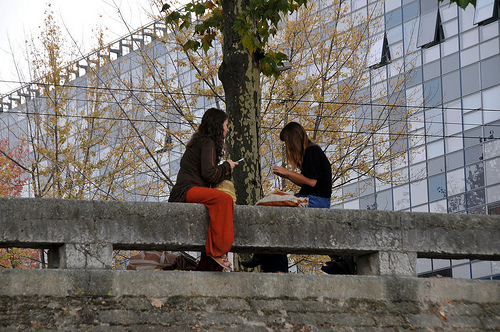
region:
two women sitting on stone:
[166, 105, 333, 270]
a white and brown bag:
[256, 189, 308, 208]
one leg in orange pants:
[185, 185, 237, 260]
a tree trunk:
[216, 0, 265, 205]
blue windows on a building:
[2, 0, 497, 216]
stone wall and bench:
[0, 194, 497, 329]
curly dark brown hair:
[188, 108, 228, 156]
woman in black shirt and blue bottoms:
[270, 121, 332, 209]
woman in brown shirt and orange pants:
[168, 106, 240, 270]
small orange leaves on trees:
[0, 0, 424, 189]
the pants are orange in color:
[178, 181, 245, 263]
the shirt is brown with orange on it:
[171, 130, 246, 193]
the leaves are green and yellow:
[233, 14, 291, 81]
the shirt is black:
[286, 144, 346, 194]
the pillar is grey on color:
[333, 204, 492, 259]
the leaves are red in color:
[3, 136, 41, 196]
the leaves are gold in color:
[311, 27, 366, 107]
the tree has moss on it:
[216, 34, 265, 140]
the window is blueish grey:
[419, 75, 447, 112]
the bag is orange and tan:
[254, 183, 314, 219]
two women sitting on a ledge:
[171, 98, 358, 277]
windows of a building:
[428, 58, 495, 101]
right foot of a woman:
[198, 250, 240, 272]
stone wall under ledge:
[19, 290, 484, 330]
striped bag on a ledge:
[257, 185, 315, 210]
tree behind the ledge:
[37, 25, 78, 191]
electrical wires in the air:
[436, 93, 498, 165]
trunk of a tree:
[217, 65, 276, 215]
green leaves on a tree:
[175, 35, 218, 52]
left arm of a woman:
[269, 161, 324, 190]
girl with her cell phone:
[163, 101, 254, 276]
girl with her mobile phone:
[166, 92, 257, 284]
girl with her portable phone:
[163, 98, 256, 290]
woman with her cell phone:
[165, 99, 247, 285]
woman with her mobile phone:
[163, 103, 259, 278]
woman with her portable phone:
[162, 99, 255, 284]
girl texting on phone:
[166, 98, 251, 274]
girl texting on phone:
[254, 112, 351, 222]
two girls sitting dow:
[147, 108, 356, 278]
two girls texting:
[136, 103, 348, 296]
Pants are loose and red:
[186, 185, 236, 258]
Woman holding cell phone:
[167, 103, 239, 270]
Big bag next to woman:
[256, 187, 313, 209]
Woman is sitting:
[163, 102, 245, 276]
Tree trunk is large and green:
[214, 0, 264, 272]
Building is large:
[0, 0, 499, 280]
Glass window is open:
[359, 33, 387, 70]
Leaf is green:
[201, 41, 211, 54]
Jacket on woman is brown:
[166, 130, 233, 200]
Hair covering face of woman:
[277, 122, 311, 169]